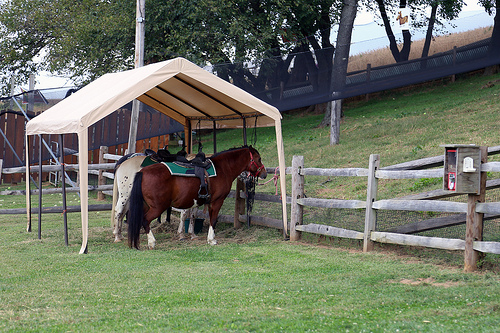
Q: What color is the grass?
A: Green.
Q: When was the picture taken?
A: Daytime.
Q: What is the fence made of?
A: Wood.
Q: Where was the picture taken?
A: At a horse ranch.